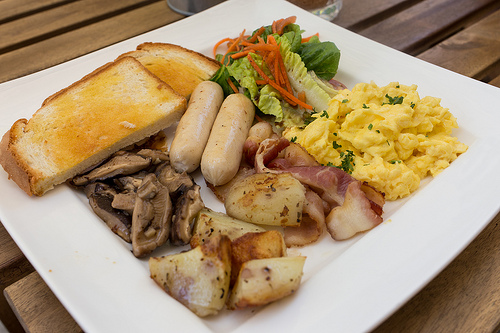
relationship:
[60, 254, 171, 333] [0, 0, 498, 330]
edge on dish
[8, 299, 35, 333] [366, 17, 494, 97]
edge on wood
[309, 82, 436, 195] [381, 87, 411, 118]
egg with herbs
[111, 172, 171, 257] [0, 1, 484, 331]
mushroom on plate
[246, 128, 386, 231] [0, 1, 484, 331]
bacon on plate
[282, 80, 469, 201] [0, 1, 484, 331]
egg on side of plate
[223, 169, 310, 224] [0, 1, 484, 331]
potato on plate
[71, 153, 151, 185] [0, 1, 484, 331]
muchrooms on plate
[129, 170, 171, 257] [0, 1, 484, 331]
mushroom on plate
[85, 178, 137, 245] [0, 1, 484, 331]
mushroom on plate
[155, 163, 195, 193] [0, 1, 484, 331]
mushroom on plate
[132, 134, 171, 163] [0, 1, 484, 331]
mushroom on plate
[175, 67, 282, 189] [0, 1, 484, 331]
sausage on plate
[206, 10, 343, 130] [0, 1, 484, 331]
salad on plate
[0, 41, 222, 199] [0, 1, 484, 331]
toast on plate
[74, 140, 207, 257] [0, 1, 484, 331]
muchrooms on plate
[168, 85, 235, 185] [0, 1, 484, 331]
links on plate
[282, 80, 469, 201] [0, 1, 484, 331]
egg on plate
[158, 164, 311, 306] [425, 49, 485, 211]
potato on plate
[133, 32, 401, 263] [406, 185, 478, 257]
food on plate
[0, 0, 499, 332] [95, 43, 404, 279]
dish full of food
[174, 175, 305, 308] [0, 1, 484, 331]
potato on plate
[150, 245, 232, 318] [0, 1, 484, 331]
potato on plate